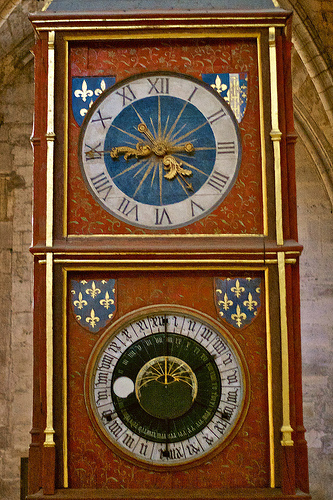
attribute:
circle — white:
[113, 377, 133, 398]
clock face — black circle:
[80, 74, 241, 230]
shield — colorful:
[70, 69, 120, 126]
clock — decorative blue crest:
[77, 64, 249, 229]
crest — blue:
[202, 69, 255, 121]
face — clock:
[89, 75, 251, 235]